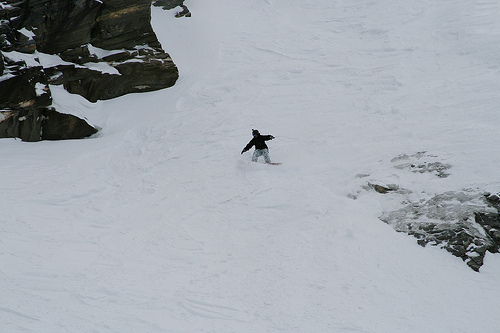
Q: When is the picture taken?
A: Daytime.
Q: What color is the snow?
A: White.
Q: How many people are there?
A: 1.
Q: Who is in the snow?
A: A person.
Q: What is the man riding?
A: A snowboard.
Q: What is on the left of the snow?
A: Rocks.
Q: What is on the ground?
A: Snow.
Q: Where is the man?
A: On a slope.